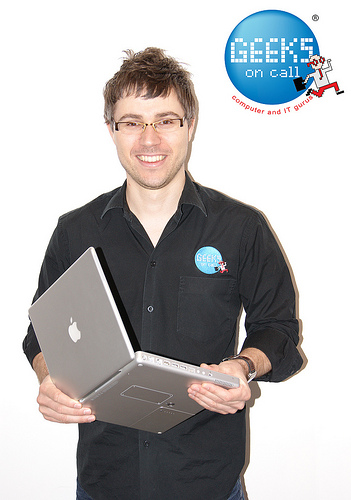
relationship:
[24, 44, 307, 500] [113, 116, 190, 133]
man wearing glasses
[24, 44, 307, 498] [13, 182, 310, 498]
man has shirt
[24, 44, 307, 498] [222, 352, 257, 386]
man wearing watch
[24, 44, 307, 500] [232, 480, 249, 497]
man wearing pants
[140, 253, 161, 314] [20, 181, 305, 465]
black buttons on shirt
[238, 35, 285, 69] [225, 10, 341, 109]
letter on logo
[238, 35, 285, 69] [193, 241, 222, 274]
letter on logo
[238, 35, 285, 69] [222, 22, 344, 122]
letter on logo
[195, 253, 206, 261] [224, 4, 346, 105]
letter on logo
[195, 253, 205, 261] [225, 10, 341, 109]
letter on logo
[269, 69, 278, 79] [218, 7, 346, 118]
letter on logo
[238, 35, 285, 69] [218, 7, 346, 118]
letter on logo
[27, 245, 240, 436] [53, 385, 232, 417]
computer in hands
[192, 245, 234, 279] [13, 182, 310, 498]
logo on shirt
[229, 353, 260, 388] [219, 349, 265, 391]
watch on wrist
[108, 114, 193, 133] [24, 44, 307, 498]
glasses on man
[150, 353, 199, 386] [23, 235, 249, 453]
ports on computer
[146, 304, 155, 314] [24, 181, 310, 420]
black buttons on shirt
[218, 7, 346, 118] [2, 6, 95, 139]
logo on wall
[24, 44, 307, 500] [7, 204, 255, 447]
man holding laptop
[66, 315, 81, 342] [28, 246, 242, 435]
logo on laptop